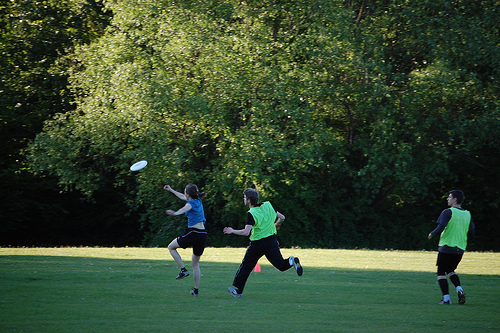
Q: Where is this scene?
A: Park.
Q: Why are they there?
A: Playing.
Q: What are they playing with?
A: Frisbee.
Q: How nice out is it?
A: Very nice.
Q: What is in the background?
A: Trees.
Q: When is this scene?
A: Daytime.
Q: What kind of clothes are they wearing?
A: Sporty.